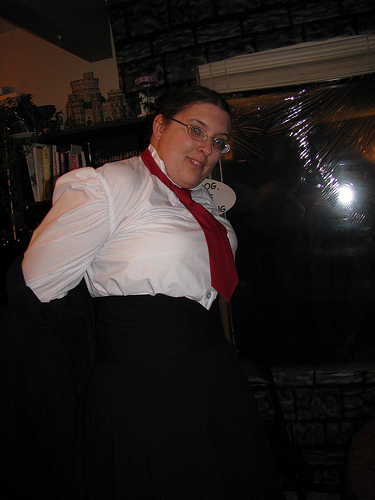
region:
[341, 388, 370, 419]
dark brick on wall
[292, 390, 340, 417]
dark brick on wall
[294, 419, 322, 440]
dark brick on wall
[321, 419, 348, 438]
dark brick on wall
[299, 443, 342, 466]
dark brick on wall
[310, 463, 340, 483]
dark brick on wall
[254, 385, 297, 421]
dark brick on wall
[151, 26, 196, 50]
dark brick on wall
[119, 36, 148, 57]
dark brick on wall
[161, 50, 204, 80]
dark brick on wall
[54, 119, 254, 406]
a lady posing for apicture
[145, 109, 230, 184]
the lady is lightskinned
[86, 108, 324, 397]
picture taken at night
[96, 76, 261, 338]
the lady is smiling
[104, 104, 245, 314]
the lady is wearing spectacles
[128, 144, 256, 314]
the tie is maroon in color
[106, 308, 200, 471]
the skirt is bl;ack in colr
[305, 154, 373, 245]
the light shines through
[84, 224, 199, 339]
the shirt is tacked in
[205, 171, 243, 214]
the poster is white in color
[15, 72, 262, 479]
woman wearing a tie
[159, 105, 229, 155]
glasses on face of woman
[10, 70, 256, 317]
woman has white shirt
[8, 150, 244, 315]
the shirt is long sleeve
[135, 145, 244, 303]
a red tie on white shirt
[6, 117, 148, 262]
a shelf behind a woman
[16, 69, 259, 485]
woman wears a black skirt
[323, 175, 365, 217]
light shines on a surface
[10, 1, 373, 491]
the room is dark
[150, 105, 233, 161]
A pair of eyeglasses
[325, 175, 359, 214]
A flash of a camera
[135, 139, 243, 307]
The tie is red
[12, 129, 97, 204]
Many books in a row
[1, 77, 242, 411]
Woman is taking her coat off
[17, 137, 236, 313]
Woman's shirt is white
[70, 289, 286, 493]
A long black skirt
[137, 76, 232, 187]
The woman has brown hair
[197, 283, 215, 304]
A button on white shirt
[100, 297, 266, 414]
a woman wearing a black skirt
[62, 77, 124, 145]
a castle sitting on a bookshelf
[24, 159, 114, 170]
books stacked in a bookshelf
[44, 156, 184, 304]
a woman wearing a white shirt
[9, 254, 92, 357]
a woman taking off her jacket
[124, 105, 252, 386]
a woman standing in front of a bookshelf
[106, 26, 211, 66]
fake brick hanging on a wall